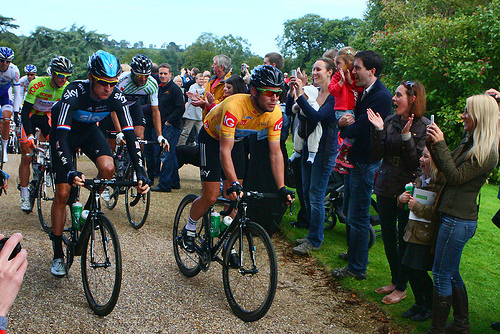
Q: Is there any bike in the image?
A: Yes, there is a bike.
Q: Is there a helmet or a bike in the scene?
A: Yes, there is a bike.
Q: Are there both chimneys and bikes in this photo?
A: No, there is a bike but no chimneys.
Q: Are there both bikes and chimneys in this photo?
A: No, there is a bike but no chimneys.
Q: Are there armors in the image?
A: No, there are no armors.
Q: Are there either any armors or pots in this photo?
A: No, there are no armors or pots.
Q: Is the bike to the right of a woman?
A: No, the bike is to the left of a woman.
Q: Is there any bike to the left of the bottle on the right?
A: Yes, there is a bike to the left of the bottle.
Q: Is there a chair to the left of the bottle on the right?
A: No, there is a bike to the left of the bottle.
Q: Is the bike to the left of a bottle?
A: Yes, the bike is to the left of a bottle.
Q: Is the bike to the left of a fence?
A: No, the bike is to the left of a bottle.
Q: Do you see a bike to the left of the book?
A: Yes, there is a bike to the left of the book.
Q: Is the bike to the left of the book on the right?
A: Yes, the bike is to the left of the book.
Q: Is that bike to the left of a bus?
A: No, the bike is to the left of the book.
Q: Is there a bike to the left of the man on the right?
A: Yes, there is a bike to the left of the man.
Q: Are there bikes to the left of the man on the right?
A: Yes, there is a bike to the left of the man.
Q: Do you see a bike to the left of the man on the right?
A: Yes, there is a bike to the left of the man.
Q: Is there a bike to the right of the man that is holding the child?
A: No, the bike is to the left of the man.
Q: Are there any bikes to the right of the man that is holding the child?
A: No, the bike is to the left of the man.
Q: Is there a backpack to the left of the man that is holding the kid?
A: No, there is a bike to the left of the man.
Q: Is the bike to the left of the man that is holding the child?
A: Yes, the bike is to the left of the man.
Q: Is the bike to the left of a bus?
A: No, the bike is to the left of the man.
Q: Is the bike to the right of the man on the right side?
A: No, the bike is to the left of the man.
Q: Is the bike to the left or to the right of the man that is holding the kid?
A: The bike is to the left of the man.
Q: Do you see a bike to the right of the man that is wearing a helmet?
A: Yes, there is a bike to the right of the man.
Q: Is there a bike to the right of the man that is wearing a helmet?
A: Yes, there is a bike to the right of the man.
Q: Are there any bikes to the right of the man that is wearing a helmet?
A: Yes, there is a bike to the right of the man.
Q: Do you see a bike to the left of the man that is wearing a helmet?
A: No, the bike is to the right of the man.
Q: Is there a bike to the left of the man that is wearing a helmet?
A: No, the bike is to the right of the man.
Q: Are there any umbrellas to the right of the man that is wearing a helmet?
A: No, there is a bike to the right of the man.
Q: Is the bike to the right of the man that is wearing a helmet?
A: Yes, the bike is to the right of the man.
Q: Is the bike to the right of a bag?
A: No, the bike is to the right of the man.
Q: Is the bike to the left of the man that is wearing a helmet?
A: No, the bike is to the right of the man.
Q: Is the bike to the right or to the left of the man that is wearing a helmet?
A: The bike is to the right of the man.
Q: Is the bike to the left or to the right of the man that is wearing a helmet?
A: The bike is to the right of the man.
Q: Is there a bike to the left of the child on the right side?
A: Yes, there is a bike to the left of the child.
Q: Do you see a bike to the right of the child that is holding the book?
A: No, the bike is to the left of the kid.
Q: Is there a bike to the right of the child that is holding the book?
A: No, the bike is to the left of the kid.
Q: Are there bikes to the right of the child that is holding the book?
A: No, the bike is to the left of the kid.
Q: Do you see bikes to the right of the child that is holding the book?
A: No, the bike is to the left of the kid.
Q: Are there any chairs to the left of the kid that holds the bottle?
A: No, there is a bike to the left of the child.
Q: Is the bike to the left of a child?
A: Yes, the bike is to the left of a child.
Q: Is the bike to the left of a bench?
A: No, the bike is to the left of a child.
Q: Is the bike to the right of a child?
A: No, the bike is to the left of a child.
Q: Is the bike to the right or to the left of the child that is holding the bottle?
A: The bike is to the left of the kid.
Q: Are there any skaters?
A: No, there are no skaters.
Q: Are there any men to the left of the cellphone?
A: Yes, there is a man to the left of the cellphone.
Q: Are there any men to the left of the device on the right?
A: Yes, there is a man to the left of the cellphone.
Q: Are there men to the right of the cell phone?
A: No, the man is to the left of the cell phone.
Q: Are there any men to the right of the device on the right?
A: No, the man is to the left of the cell phone.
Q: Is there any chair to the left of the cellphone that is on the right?
A: No, there is a man to the left of the mobile phone.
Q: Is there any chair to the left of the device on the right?
A: No, there is a man to the left of the mobile phone.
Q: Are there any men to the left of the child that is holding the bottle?
A: Yes, there is a man to the left of the kid.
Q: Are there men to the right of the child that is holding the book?
A: No, the man is to the left of the kid.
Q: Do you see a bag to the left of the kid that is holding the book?
A: No, there is a man to the left of the kid.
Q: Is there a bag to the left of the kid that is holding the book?
A: No, there is a man to the left of the kid.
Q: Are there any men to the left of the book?
A: Yes, there is a man to the left of the book.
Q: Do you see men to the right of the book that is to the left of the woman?
A: No, the man is to the left of the book.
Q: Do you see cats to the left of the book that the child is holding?
A: No, there is a man to the left of the book.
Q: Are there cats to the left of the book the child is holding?
A: No, there is a man to the left of the book.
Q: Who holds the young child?
A: The man holds the child.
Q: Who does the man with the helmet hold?
A: The man holds the kid.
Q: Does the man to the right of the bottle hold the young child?
A: Yes, the man holds the kid.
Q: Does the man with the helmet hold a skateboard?
A: No, the man holds the kid.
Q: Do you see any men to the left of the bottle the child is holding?
A: Yes, there is a man to the left of the bottle.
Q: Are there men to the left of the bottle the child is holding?
A: Yes, there is a man to the left of the bottle.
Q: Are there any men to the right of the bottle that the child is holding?
A: No, the man is to the left of the bottle.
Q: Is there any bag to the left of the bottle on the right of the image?
A: No, there is a man to the left of the bottle.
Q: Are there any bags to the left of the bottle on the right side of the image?
A: No, there is a man to the left of the bottle.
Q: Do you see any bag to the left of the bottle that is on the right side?
A: No, there is a man to the left of the bottle.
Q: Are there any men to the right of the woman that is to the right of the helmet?
A: Yes, there is a man to the right of the woman.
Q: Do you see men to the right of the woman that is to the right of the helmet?
A: Yes, there is a man to the right of the woman.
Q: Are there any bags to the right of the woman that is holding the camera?
A: No, there is a man to the right of the woman.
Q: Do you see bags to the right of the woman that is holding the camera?
A: No, there is a man to the right of the woman.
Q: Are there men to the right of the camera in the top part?
A: Yes, there is a man to the right of the camera.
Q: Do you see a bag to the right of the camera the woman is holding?
A: No, there is a man to the right of the camera.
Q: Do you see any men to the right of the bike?
A: Yes, there is a man to the right of the bike.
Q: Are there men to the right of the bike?
A: Yes, there is a man to the right of the bike.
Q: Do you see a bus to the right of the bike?
A: No, there is a man to the right of the bike.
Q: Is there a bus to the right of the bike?
A: No, there is a man to the right of the bike.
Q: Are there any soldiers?
A: No, there are no soldiers.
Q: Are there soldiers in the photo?
A: No, there are no soldiers.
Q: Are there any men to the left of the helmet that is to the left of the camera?
A: Yes, there is a man to the left of the helmet.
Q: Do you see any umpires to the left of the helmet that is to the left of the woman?
A: No, there is a man to the left of the helmet.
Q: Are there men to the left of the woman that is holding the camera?
A: Yes, there is a man to the left of the woman.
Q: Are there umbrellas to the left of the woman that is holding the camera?
A: No, there is a man to the left of the woman.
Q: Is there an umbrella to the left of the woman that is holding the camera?
A: No, there is a man to the left of the woman.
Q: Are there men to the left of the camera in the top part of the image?
A: Yes, there is a man to the left of the camera.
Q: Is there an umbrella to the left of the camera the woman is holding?
A: No, there is a man to the left of the camera.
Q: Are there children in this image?
A: Yes, there is a child.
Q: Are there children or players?
A: Yes, there is a child.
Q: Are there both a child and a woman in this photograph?
A: Yes, there are both a child and a woman.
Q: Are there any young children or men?
A: Yes, there is a young child.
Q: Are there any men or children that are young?
A: Yes, the child is young.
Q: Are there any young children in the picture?
A: Yes, there is a young child.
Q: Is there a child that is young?
A: Yes, there is a child that is young.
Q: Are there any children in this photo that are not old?
A: Yes, there is an young child.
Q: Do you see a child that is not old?
A: Yes, there is an young child.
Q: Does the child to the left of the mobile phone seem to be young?
A: Yes, the child is young.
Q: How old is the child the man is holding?
A: The kid is young.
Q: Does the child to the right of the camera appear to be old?
A: No, the child is young.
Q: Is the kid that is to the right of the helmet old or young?
A: The kid is young.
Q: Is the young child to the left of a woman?
A: Yes, the child is to the left of a woman.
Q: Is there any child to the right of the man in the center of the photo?
A: Yes, there is a child to the right of the man.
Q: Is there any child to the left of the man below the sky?
A: No, the child is to the right of the man.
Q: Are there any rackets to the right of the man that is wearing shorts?
A: No, there is a child to the right of the man.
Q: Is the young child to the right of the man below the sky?
A: Yes, the kid is to the right of the man.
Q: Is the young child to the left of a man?
A: No, the kid is to the right of a man.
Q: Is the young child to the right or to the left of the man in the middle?
A: The kid is to the right of the man.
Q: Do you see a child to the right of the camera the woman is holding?
A: Yes, there is a child to the right of the camera.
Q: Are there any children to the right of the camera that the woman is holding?
A: Yes, there is a child to the right of the camera.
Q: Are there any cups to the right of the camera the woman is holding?
A: No, there is a child to the right of the camera.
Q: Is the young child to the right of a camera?
A: Yes, the child is to the right of a camera.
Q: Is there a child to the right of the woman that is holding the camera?
A: Yes, there is a child to the right of the woman.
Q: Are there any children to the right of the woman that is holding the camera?
A: Yes, there is a child to the right of the woman.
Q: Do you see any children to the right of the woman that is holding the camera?
A: Yes, there is a child to the right of the woman.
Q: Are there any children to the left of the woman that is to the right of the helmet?
A: No, the child is to the right of the woman.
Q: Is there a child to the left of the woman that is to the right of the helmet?
A: No, the child is to the right of the woman.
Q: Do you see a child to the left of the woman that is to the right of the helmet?
A: No, the child is to the right of the woman.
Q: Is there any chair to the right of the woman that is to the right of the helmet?
A: No, there is a child to the right of the woman.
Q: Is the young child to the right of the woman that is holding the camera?
A: Yes, the child is to the right of the woman.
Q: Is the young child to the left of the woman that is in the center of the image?
A: No, the kid is to the right of the woman.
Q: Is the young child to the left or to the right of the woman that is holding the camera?
A: The kid is to the right of the woman.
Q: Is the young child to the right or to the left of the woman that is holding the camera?
A: The kid is to the right of the woman.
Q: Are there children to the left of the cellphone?
A: Yes, there is a child to the left of the cellphone.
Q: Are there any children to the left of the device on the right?
A: Yes, there is a child to the left of the cellphone.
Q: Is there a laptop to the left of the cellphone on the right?
A: No, there is a child to the left of the cell phone.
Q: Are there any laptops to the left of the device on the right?
A: No, there is a child to the left of the cell phone.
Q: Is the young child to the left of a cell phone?
A: Yes, the child is to the left of a cell phone.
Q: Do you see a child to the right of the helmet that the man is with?
A: Yes, there is a child to the right of the helmet.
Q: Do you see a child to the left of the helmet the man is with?
A: No, the child is to the right of the helmet.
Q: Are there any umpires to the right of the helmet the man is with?
A: No, there is a child to the right of the helmet.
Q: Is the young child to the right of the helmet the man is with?
A: Yes, the kid is to the right of the helmet.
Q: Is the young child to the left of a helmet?
A: No, the child is to the right of a helmet.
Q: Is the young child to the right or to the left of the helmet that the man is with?
A: The child is to the right of the helmet.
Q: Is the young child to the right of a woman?
A: No, the child is to the left of a woman.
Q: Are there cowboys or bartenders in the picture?
A: No, there are no bartenders or cowboys.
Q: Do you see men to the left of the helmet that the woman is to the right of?
A: Yes, there is a man to the left of the helmet.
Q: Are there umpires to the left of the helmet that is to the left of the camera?
A: No, there is a man to the left of the helmet.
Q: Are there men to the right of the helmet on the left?
A: Yes, there is a man to the right of the helmet.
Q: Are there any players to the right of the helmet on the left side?
A: No, there is a man to the right of the helmet.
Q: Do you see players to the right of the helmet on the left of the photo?
A: No, there is a man to the right of the helmet.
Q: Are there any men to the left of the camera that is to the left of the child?
A: Yes, there is a man to the left of the camera.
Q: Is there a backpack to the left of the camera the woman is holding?
A: No, there is a man to the left of the camera.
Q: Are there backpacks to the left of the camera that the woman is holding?
A: No, there is a man to the left of the camera.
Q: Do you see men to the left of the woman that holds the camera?
A: Yes, there is a man to the left of the woman.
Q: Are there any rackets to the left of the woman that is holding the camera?
A: No, there is a man to the left of the woman.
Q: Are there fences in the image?
A: No, there are no fences.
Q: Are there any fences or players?
A: No, there are no fences or players.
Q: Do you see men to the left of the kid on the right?
A: Yes, there is a man to the left of the child.